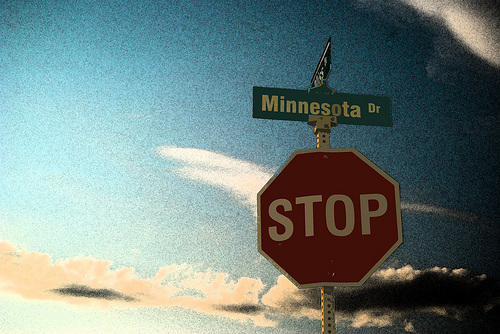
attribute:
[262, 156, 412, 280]
sign — red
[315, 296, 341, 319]
pole — metal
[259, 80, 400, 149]
street sign — green, small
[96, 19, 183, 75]
sky — blue